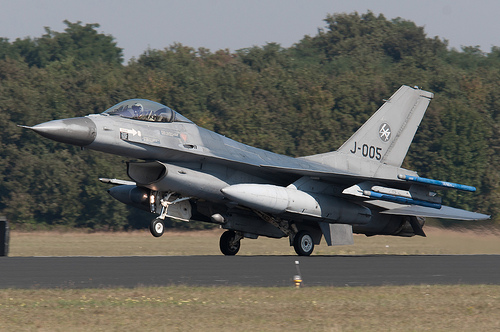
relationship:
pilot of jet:
[128, 98, 142, 120] [17, 55, 498, 265]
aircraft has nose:
[16, 84, 491, 255] [15, 121, 34, 130]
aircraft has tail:
[16, 84, 491, 255] [333, 80, 438, 163]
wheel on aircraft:
[149, 219, 165, 237] [16, 84, 491, 255]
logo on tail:
[375, 119, 393, 143] [337, 85, 434, 168]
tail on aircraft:
[337, 85, 434, 168] [16, 84, 491, 255]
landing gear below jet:
[3, 256, 497, 282] [17, 85, 483, 209]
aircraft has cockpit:
[16, 84, 491, 255] [103, 100, 193, 125]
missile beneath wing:
[218, 179, 374, 226] [258, 163, 477, 208]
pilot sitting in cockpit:
[128, 102, 143, 119] [101, 87, 199, 153]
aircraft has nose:
[16, 84, 491, 255] [3, 100, 80, 160]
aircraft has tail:
[16, 84, 491, 255] [337, 83, 433, 167]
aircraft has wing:
[16, 84, 491, 255] [251, 158, 444, 190]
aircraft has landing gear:
[16, 82, 491, 254] [218, 230, 313, 255]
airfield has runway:
[0, 217, 495, 330] [0, 252, 497, 287]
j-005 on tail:
[349, 142, 384, 161] [346, 83, 438, 165]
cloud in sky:
[0, 0, 498, 67] [3, 0, 499, 64]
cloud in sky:
[3, 2, 495, 62] [3, 0, 499, 64]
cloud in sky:
[3, 2, 495, 62] [444, 10, 487, 40]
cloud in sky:
[0, 0, 498, 67] [2, 0, 498, 56]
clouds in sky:
[131, 5, 250, 35] [3, 0, 499, 64]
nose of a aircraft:
[18, 115, 98, 146] [16, 84, 491, 255]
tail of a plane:
[337, 83, 433, 167] [16, 82, 492, 256]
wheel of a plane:
[152, 216, 167, 238] [16, 82, 492, 256]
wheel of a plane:
[218, 225, 242, 257] [16, 82, 492, 256]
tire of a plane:
[294, 230, 314, 255] [16, 82, 492, 256]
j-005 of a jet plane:
[350, 141, 382, 160] [50, 85, 417, 260]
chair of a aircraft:
[143, 108, 154, 119] [16, 84, 491, 255]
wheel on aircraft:
[219, 230, 240, 255] [16, 84, 491, 255]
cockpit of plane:
[98, 94, 198, 125] [31, 79, 473, 280]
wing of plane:
[134, 135, 481, 215] [7, 69, 499, 284]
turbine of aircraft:
[216, 173, 388, 231] [16, 84, 491, 255]